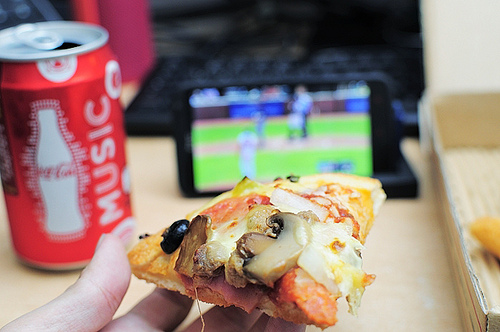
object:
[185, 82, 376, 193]
screen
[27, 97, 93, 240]
bottle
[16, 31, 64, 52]
tab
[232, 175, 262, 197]
pepper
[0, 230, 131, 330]
finger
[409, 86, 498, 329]
box top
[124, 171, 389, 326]
slice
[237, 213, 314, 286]
mushroom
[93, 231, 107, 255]
fingernail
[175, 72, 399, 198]
cell phone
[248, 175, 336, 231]
plate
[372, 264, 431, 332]
table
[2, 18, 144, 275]
can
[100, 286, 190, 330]
finger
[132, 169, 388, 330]
pizza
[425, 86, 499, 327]
box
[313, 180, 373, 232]
cheese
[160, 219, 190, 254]
olive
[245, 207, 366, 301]
vegetables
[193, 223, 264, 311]
meat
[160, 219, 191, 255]
black olives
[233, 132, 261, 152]
part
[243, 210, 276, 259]
part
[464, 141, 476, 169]
part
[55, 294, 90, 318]
part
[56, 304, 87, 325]
part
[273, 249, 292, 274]
part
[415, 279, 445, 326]
part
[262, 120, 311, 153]
part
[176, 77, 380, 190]
baseball game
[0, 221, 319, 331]
hand